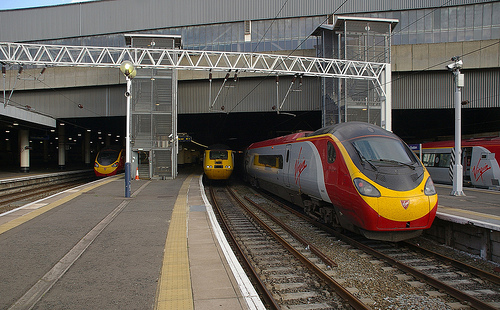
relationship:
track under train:
[208, 180, 498, 309] [201, 143, 234, 184]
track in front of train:
[0, 175, 104, 214] [92, 145, 123, 180]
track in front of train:
[208, 180, 498, 309] [242, 119, 438, 243]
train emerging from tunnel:
[201, 143, 234, 184] [178, 112, 320, 173]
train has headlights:
[242, 119, 438, 243] [353, 176, 436, 197]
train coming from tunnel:
[243, 121, 438, 243] [1, 109, 499, 180]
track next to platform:
[208, 180, 498, 309] [0, 174, 266, 309]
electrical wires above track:
[220, 0, 499, 128] [208, 180, 498, 309]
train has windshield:
[201, 143, 234, 184] [208, 150, 227, 159]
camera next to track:
[446, 55, 463, 72] [208, 180, 498, 309]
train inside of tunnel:
[243, 121, 438, 243] [1, 109, 499, 180]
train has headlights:
[92, 145, 123, 180] [92, 162, 117, 168]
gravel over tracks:
[205, 182, 499, 310] [0, 176, 499, 309]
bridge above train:
[1, 1, 498, 70] [243, 121, 438, 243]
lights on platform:
[119, 59, 136, 197] [0, 174, 266, 309]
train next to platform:
[201, 143, 234, 184] [0, 174, 266, 309]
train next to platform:
[92, 145, 123, 180] [0, 174, 266, 309]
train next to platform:
[406, 136, 499, 190] [419, 182, 499, 263]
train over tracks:
[242, 119, 438, 243] [0, 176, 499, 309]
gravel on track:
[205, 182, 499, 310] [219, 176, 434, 300]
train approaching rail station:
[242, 119, 438, 243] [235, 71, 497, 242]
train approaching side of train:
[201, 143, 234, 184] [0, 0, 500, 310]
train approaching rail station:
[92, 145, 123, 180] [71, 37, 480, 256]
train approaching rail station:
[406, 136, 499, 190] [42, 82, 461, 256]